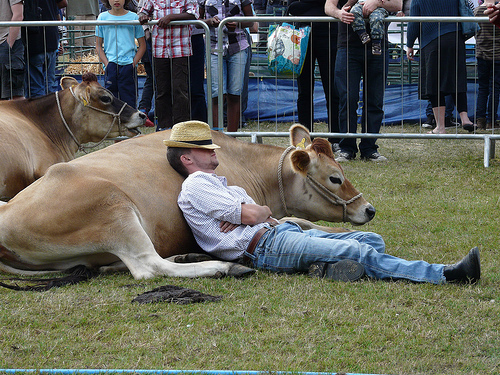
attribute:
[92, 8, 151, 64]
shirt — blue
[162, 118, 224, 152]
fedora — tan, straw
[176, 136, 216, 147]
band — black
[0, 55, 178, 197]
cow — brown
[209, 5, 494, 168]
fence — metal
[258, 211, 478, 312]
jeans — blue 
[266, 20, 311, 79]
bag — blue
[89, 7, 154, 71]
shirt — blue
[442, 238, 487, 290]
shoes — black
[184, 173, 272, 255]
shirt — plaid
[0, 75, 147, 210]
cow — brown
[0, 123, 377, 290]
cow — brown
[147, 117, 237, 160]
hat — straw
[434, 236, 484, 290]
boots — black 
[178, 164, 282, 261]
shirt — light blue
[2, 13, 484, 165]
barriers — metal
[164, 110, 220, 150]
hat — straw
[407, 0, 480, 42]
shirt — black